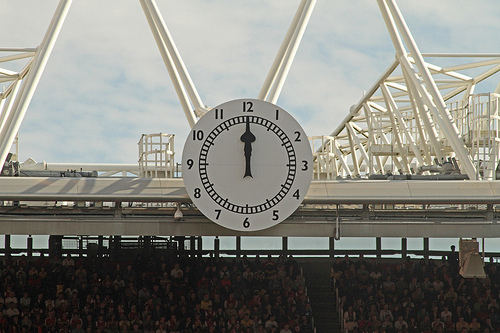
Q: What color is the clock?
A: White.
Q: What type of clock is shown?
A: Analog.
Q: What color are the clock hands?
A: Black.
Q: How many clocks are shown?
A: 1.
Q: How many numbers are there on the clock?
A: 12.